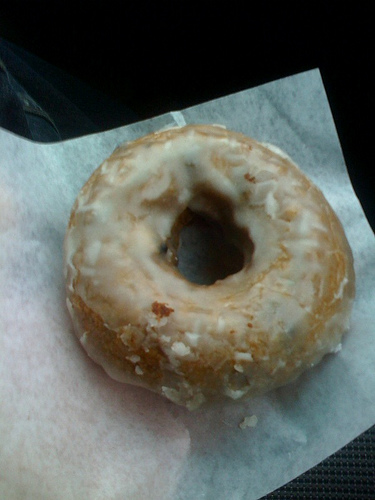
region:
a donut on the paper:
[86, 127, 319, 418]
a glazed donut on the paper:
[71, 135, 367, 459]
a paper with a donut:
[49, 104, 372, 396]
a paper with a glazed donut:
[37, 108, 324, 477]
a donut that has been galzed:
[35, 109, 345, 490]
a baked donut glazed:
[7, 94, 371, 404]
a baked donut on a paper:
[76, 118, 372, 489]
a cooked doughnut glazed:
[43, 179, 353, 445]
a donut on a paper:
[39, 182, 374, 449]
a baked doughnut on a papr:
[56, 219, 350, 481]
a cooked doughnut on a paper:
[32, 201, 351, 444]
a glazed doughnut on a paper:
[62, 157, 372, 406]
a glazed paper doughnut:
[62, 177, 290, 424]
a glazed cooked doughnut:
[29, 183, 334, 418]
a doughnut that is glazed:
[52, 178, 353, 438]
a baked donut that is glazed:
[43, 174, 365, 392]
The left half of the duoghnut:
[64, 147, 211, 414]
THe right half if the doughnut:
[185, 107, 351, 427]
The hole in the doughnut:
[161, 211, 243, 289]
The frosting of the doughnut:
[66, 132, 346, 405]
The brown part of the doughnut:
[95, 118, 329, 396]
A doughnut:
[55, 134, 346, 431]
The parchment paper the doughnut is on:
[4, 95, 357, 462]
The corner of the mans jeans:
[5, 70, 59, 138]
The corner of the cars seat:
[240, 420, 363, 496]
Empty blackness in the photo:
[60, 5, 346, 137]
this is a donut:
[18, 25, 316, 443]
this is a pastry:
[72, 189, 337, 390]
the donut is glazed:
[72, 123, 297, 314]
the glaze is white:
[76, 167, 265, 330]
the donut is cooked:
[89, 96, 304, 310]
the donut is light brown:
[71, 282, 240, 397]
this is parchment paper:
[15, 356, 193, 482]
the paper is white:
[20, 384, 152, 480]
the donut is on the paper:
[26, 104, 335, 346]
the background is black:
[19, 60, 96, 110]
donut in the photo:
[30, 134, 354, 353]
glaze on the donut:
[132, 286, 282, 386]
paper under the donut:
[54, 394, 129, 451]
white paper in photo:
[18, 390, 110, 450]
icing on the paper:
[230, 404, 273, 435]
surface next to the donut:
[319, 447, 366, 492]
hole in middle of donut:
[161, 182, 250, 262]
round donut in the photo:
[28, 102, 266, 398]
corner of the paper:
[255, 38, 351, 122]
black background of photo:
[107, 17, 223, 83]